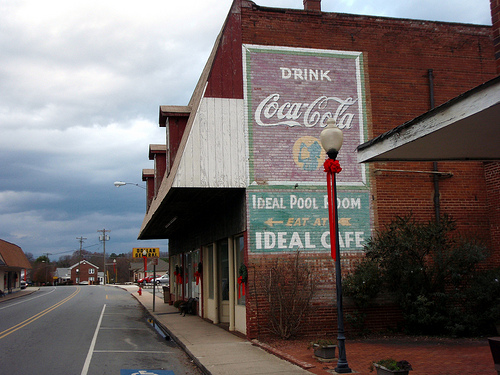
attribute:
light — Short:
[307, 119, 354, 354]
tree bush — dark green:
[365, 212, 472, 316]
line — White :
[69, 300, 111, 375]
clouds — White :
[1, 5, 227, 179]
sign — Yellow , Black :
[132, 244, 161, 259]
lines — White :
[0, 283, 83, 343]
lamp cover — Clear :
[317, 117, 343, 161]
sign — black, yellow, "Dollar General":
[132, 246, 158, 257]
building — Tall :
[138, 1, 498, 343]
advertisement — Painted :
[241, 45, 371, 259]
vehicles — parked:
[131, 270, 172, 297]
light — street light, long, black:
[289, 109, 381, 339]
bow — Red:
[271, 101, 411, 268]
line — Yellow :
[13, 288, 73, 343]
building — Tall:
[228, 23, 407, 279]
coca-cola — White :
[252, 89, 356, 131]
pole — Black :
[323, 157, 343, 263]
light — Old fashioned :
[320, 120, 350, 370]